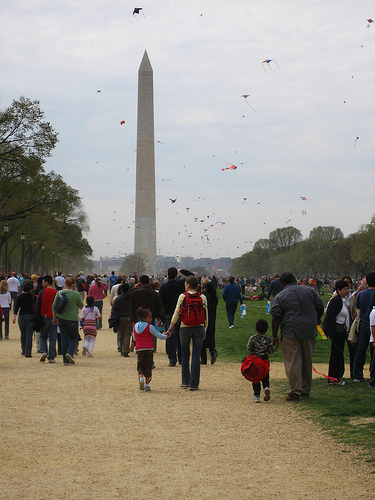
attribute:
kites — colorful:
[165, 150, 264, 253]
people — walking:
[19, 259, 142, 348]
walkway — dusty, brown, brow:
[24, 391, 222, 475]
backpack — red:
[176, 291, 210, 329]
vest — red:
[132, 328, 158, 353]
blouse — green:
[52, 285, 84, 320]